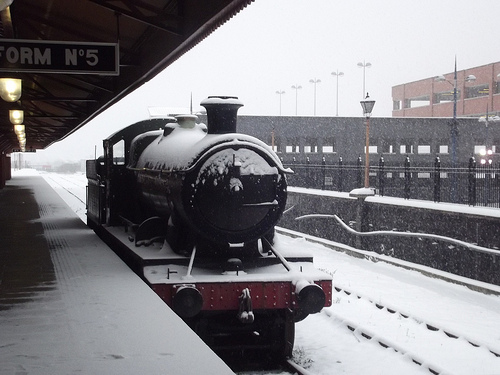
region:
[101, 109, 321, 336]
train at the station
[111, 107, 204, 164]
snow on the train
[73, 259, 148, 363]
station for the train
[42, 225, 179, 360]
snow on the station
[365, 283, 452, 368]
track for the train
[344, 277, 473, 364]
snow on the tracks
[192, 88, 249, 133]
stack of the train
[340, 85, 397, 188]
pole on the fence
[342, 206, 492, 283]
fence on the side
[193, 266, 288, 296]
the front is red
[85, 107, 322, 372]
engine of a train in the snow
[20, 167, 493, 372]
train tracks are covered in snow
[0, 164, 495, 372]
fresh snow on the ground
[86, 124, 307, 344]
engine of the train is black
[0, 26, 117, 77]
sign under the strain station awning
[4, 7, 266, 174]
awning over the train station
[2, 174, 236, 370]
sidewalk next to the tracks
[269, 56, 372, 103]
street light poles in the distance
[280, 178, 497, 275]
fence next to the train tracks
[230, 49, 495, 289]
two buildings in the distance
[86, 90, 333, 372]
Black and red train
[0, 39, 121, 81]
Black and white hanging sign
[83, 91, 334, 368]
Train covered in snow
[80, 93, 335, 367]
Train on train tracks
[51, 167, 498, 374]
Snow covered train tracks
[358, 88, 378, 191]
Black lamp with metal post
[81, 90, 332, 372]
Black train covered in snow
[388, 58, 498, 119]
Tall brick parking garage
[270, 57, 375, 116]
Five metal parking lot lamps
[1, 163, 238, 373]
Walkway next to train tracks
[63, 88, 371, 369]
train with only one car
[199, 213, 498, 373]
snow on the tracks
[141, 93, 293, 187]
snow on top of the train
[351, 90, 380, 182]
light on top of a pole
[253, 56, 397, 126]
a row of lampposts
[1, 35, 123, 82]
sign hanging down from the ceiling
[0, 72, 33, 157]
lights on the ceiling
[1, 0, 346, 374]
train at the station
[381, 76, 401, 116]
corner of a building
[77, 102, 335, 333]
train on the track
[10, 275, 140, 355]
platform near the train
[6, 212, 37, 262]
platform without the snow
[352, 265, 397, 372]
snow on the track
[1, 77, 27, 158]
lights on the platform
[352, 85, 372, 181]
light on the track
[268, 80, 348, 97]
lights in the distance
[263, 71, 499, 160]
buildings next to track